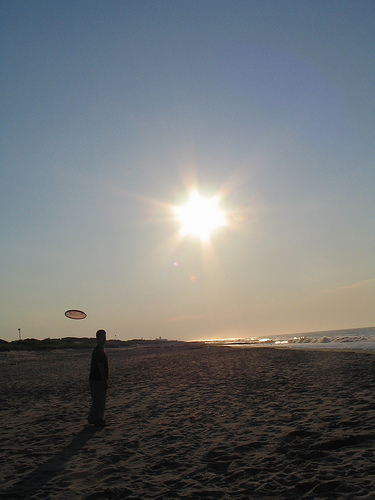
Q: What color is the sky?
A: Blue.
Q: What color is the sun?
A: Yellow.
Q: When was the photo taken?
A: Sundown.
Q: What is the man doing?
A: Playing frisbee.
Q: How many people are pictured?
A: One.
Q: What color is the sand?
A: Brown.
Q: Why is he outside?
A: To play frisbee.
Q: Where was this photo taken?
A: At the beach.